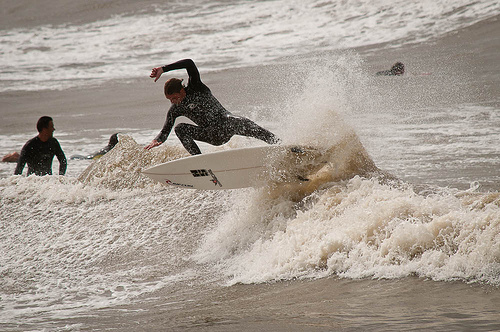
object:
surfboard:
[140, 145, 305, 190]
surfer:
[141, 59, 285, 156]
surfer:
[13, 114, 67, 177]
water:
[1, 1, 499, 331]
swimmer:
[374, 62, 407, 78]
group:
[13, 58, 286, 176]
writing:
[207, 169, 223, 187]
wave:
[1, 1, 499, 96]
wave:
[1, 140, 499, 288]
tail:
[289, 144, 330, 184]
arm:
[158, 107, 177, 144]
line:
[141, 165, 267, 176]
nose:
[139, 165, 154, 181]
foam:
[187, 174, 499, 286]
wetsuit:
[153, 58, 279, 155]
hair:
[164, 78, 186, 95]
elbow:
[182, 58, 195, 69]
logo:
[190, 169, 208, 177]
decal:
[186, 103, 198, 111]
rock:
[0, 151, 21, 163]